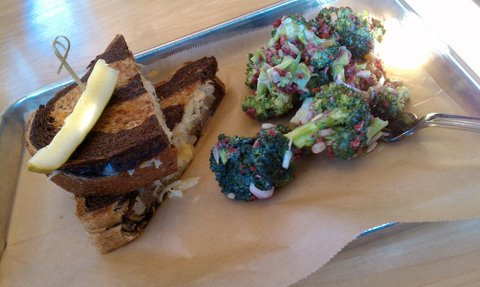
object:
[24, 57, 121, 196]
pickle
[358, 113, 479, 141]
fork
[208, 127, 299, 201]
broccoli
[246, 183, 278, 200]
onions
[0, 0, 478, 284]
paper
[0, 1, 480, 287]
tray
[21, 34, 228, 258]
bread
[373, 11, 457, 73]
light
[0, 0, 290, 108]
table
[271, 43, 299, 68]
peppers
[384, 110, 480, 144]
steel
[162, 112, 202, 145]
sauerkraut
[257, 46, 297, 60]
bacon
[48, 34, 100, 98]
toothpick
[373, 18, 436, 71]
cream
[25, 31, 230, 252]
sandwich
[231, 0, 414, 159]
salad